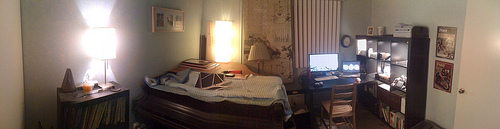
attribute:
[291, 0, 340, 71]
wall — striped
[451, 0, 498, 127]
door — is closed, is white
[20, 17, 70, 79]
wall — white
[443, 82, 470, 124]
wall — white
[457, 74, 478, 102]
handle — white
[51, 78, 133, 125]
bookcase — brown, wooden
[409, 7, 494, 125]
wall — white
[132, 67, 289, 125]
bed — poorly spread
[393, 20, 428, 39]
white printer — on top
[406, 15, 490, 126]
wall — white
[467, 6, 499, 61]
wall — white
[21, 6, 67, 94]
wall — white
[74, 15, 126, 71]
light — sharp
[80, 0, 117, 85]
wall lights — bright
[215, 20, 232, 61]
wall lights — bright